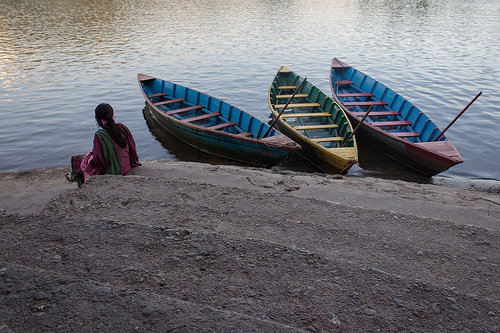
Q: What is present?
A: Boats.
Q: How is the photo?
A: Clear.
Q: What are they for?
A: Transport.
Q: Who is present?
A: A woman.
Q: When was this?
A: Daytime.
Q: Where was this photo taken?
A: Near a body of water.